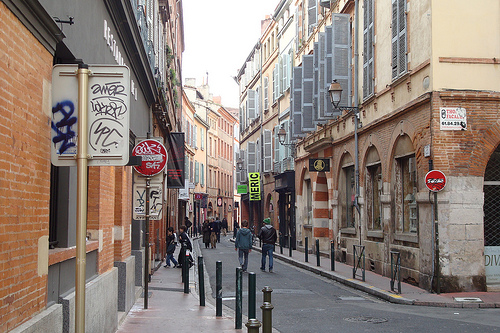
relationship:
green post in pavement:
[243, 268, 261, 330] [128, 301, 241, 331]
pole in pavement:
[233, 266, 240, 333] [175, 282, 213, 315]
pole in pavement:
[214, 258, 223, 319] [172, 299, 214, 329]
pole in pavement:
[196, 252, 206, 307] [172, 299, 214, 329]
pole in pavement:
[233, 266, 240, 333] [172, 299, 214, 329]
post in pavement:
[312, 236, 322, 271] [172, 299, 214, 329]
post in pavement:
[290, 235, 293, 256] [172, 299, 214, 329]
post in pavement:
[303, 234, 312, 266] [175, 299, 203, 324]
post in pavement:
[281, 222, 311, 264] [274, 258, 343, 331]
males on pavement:
[234, 215, 277, 268] [185, 228, 498, 331]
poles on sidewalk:
[184, 247, 279, 327] [157, 285, 250, 330]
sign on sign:
[248, 170, 261, 201] [246, 172, 261, 203]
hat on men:
[252, 212, 276, 224] [260, 217, 278, 272]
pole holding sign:
[70, 57, 93, 329] [45, 60, 129, 174]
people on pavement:
[166, 225, 191, 260] [114, 308, 242, 333]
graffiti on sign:
[63, 61, 133, 171] [45, 64, 138, 180]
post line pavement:
[182, 246, 191, 296] [274, 258, 343, 331]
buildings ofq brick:
[7, 1, 499, 332] [6, 215, 21, 229]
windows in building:
[40, 66, 137, 275] [313, 2, 499, 299]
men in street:
[229, 220, 276, 272] [197, 214, 495, 333]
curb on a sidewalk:
[271, 245, 493, 312] [129, 194, 369, 331]